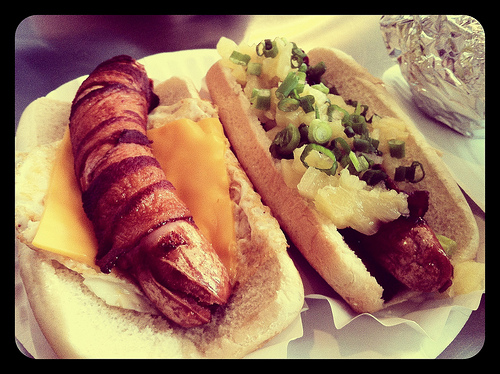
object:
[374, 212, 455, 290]
ketchup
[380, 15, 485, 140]
foil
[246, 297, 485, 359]
paper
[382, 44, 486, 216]
paper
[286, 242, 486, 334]
doily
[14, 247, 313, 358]
doily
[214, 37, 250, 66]
onion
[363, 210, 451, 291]
hot dog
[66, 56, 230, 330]
bacon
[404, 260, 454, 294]
tip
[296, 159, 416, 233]
onions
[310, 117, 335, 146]
slice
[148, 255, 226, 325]
split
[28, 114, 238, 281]
cheese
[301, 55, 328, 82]
onion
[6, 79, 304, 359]
bun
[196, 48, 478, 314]
bun